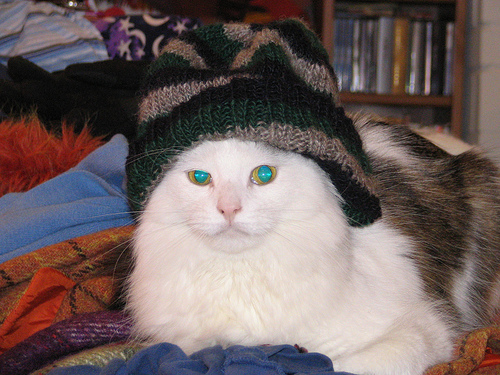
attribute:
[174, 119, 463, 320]
cat — white, indoors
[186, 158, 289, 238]
eyes — blue, oval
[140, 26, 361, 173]
hat — green, striped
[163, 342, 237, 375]
blankets — purple, blue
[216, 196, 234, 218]
nose — pink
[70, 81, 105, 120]
blankets — brown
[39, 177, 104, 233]
clothing — blue